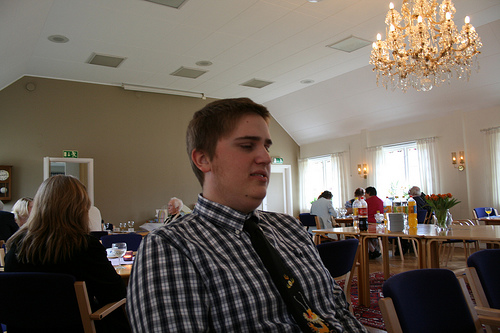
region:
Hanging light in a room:
[366, 0, 481, 92]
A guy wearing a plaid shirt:
[123, 95, 368, 331]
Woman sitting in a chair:
[0, 175, 127, 332]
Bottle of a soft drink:
[405, 193, 418, 228]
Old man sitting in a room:
[160, 198, 184, 223]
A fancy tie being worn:
[242, 217, 332, 331]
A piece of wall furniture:
[0, 163, 12, 200]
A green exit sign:
[62, 149, 77, 158]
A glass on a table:
[126, 220, 135, 229]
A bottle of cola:
[355, 195, 368, 233]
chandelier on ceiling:
[364, 5, 489, 97]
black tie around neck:
[233, 214, 340, 331]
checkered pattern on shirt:
[163, 252, 256, 304]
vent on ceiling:
[79, 45, 135, 76]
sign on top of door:
[52, 143, 86, 157]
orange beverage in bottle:
[397, 188, 423, 230]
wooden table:
[307, 212, 498, 314]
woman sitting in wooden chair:
[5, 173, 132, 331]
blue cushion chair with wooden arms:
[367, 256, 498, 330]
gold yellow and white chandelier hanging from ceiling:
[366, 0, 484, 95]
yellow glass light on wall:
[447, 145, 467, 173]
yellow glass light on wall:
[353, 160, 369, 182]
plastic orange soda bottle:
[404, 188, 420, 234]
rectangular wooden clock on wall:
[1, 160, 14, 203]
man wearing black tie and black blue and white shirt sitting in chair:
[123, 93, 389, 331]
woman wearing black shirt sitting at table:
[2, 170, 150, 331]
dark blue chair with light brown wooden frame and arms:
[375, 264, 495, 331]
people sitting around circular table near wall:
[298, 183, 457, 265]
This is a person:
[363, 179, 382, 227]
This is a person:
[397, 177, 449, 252]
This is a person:
[348, 182, 371, 224]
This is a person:
[308, 182, 349, 244]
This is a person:
[131, 90, 313, 322]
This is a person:
[25, 165, 100, 330]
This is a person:
[155, 178, 186, 238]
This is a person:
[9, 171, 46, 249]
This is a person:
[168, 84, 315, 326]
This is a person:
[308, 170, 351, 252]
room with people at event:
[19, 118, 498, 313]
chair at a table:
[378, 260, 484, 327]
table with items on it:
[328, 210, 499, 251]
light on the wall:
[351, 147, 372, 177]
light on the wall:
[446, 145, 471, 167]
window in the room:
[368, 148, 440, 189]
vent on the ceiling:
[229, 70, 294, 92]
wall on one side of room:
[33, 98, 178, 138]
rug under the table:
[358, 260, 422, 310]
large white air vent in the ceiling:
[167, 61, 209, 82]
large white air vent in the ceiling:
[84, 46, 131, 71]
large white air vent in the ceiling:
[325, 29, 377, 56]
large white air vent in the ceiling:
[237, 73, 276, 91]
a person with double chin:
[114, 81, 384, 331]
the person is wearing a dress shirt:
[133, 85, 372, 330]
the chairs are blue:
[380, 248, 499, 332]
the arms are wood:
[76, 268, 128, 332]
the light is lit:
[356, 0, 486, 96]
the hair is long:
[0, 164, 101, 272]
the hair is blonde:
[0, 170, 121, 270]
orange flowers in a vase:
[423, 186, 459, 232]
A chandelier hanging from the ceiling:
[365, 0, 487, 97]